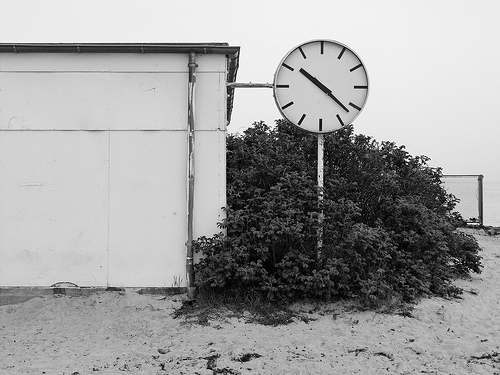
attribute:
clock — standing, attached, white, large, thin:
[269, 38, 372, 139]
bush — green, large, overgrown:
[188, 121, 476, 306]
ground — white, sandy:
[2, 285, 498, 372]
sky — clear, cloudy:
[1, 0, 495, 182]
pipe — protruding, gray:
[183, 52, 204, 300]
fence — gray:
[350, 159, 493, 237]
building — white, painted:
[1, 35, 273, 284]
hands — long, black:
[296, 63, 352, 114]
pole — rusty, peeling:
[309, 133, 327, 277]